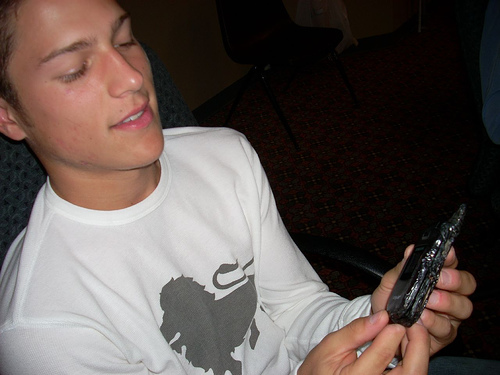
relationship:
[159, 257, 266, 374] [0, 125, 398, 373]
lion on front of shirt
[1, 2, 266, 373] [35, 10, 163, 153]
boy has face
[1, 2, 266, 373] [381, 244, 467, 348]
boy has hand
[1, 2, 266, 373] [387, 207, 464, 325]
boy staring at phone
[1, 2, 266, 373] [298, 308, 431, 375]
boy has hand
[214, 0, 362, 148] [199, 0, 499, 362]
chair sitting on ground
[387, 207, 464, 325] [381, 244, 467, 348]
phone held in hand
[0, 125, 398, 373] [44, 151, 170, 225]
shirt has collar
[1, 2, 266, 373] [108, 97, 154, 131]
boy has mouth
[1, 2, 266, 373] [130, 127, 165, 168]
boy has chin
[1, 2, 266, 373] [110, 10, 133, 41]
boy has left eyebrow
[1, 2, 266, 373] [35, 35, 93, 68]
boy has right eyebrow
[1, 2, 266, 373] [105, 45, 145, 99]
boy has nose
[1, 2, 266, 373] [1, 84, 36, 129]
boy has side burn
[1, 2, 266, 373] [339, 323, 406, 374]
boy has finger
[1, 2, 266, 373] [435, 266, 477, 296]
boy has finger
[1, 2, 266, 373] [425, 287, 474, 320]
boy has finger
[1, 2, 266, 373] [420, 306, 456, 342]
boy has finger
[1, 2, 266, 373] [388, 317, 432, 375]
boy has finger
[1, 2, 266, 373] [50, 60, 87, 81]
boy has eye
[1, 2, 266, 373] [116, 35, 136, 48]
boy has eye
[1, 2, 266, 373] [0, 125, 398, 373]
boy has shirt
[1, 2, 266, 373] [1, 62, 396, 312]
boy sitting on chair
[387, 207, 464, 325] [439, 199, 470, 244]
phone has antenna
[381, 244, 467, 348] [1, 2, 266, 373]
hand of boy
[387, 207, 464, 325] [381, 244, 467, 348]
phone in hand